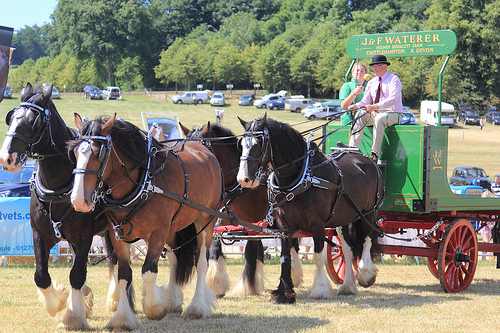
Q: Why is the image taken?
A: Remembrance.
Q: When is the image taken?
A: While travelling.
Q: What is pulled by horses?
A: Wagon.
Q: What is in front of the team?
A: Brown horses.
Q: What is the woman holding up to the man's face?
A: A microphone.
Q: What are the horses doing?
A: Pulling a carriage.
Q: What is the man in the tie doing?
A: Steering some horses.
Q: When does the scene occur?
A: Daytime.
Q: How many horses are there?
A: Four.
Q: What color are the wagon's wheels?
A: Red.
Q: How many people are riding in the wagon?
A: Two.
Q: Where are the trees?
A: Behind the wagon.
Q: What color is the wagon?
A: Green.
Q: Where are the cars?
A: Parked in front of the trees.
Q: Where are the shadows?
A: On the grass.